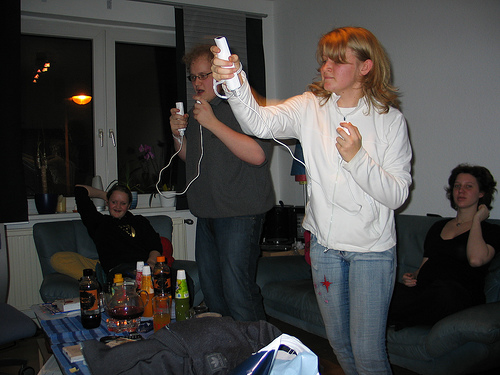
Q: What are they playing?
A: The wii.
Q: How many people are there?
A: 4.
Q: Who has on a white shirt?
A: Girl holding controller.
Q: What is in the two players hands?
A: A wii controller.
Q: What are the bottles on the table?
A: Drinks.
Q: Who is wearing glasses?
A: The man.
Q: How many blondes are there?
A: 1.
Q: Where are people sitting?
A: On loveseat and couch.